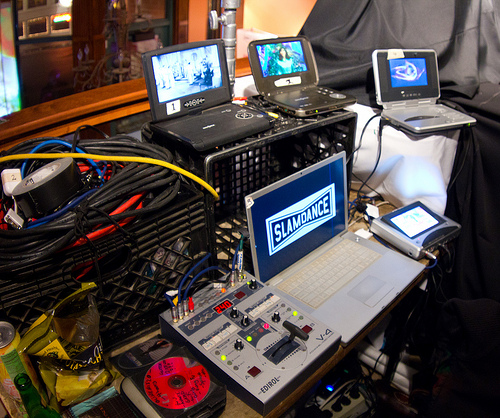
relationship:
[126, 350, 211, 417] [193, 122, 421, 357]
disc near laptop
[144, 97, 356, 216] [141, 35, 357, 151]
black crate under dvd players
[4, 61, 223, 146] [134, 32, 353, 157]
ledge behind dvd players